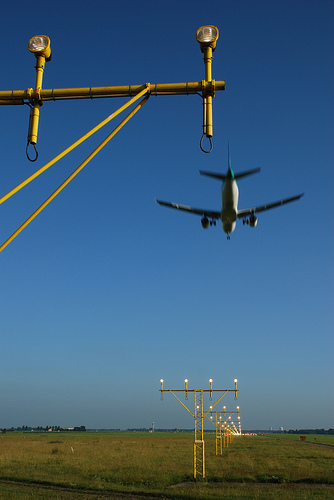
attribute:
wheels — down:
[206, 215, 252, 238]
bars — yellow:
[158, 388, 252, 480]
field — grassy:
[10, 437, 333, 478]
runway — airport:
[227, 425, 333, 465]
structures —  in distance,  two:
[265, 424, 283, 430]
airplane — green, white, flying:
[151, 156, 307, 240]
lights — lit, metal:
[155, 374, 243, 400]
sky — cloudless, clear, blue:
[57, 250, 181, 350]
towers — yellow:
[5, 57, 231, 161]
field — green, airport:
[88, 436, 166, 486]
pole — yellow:
[158, 387, 239, 478]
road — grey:
[315, 441, 325, 447]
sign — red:
[299, 435, 308, 443]